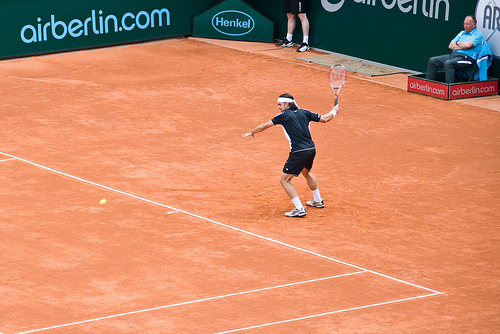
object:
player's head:
[277, 92, 294, 112]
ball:
[99, 198, 107, 204]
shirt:
[270, 109, 321, 153]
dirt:
[1, 39, 498, 332]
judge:
[426, 15, 483, 84]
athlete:
[240, 92, 340, 217]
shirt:
[451, 27, 484, 60]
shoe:
[306, 199, 325, 208]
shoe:
[283, 207, 307, 217]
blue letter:
[151, 7, 172, 27]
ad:
[18, 7, 173, 44]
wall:
[0, 0, 500, 85]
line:
[5, 270, 443, 334]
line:
[0, 153, 443, 298]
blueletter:
[20, 24, 37, 43]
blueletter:
[136, 10, 151, 30]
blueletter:
[121, 12, 136, 30]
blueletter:
[105, 14, 119, 33]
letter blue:
[19, 8, 171, 45]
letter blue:
[211, 10, 256, 37]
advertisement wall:
[190, 2, 273, 43]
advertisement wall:
[0, 0, 199, 60]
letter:
[68, 18, 84, 37]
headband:
[277, 97, 300, 109]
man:
[275, 0, 311, 53]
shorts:
[282, 0, 309, 13]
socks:
[291, 188, 322, 210]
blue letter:
[482, 5, 491, 30]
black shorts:
[282, 148, 317, 177]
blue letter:
[91, 9, 99, 34]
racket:
[327, 62, 348, 114]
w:
[332, 71, 343, 81]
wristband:
[329, 109, 337, 117]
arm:
[306, 110, 336, 123]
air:
[2, 3, 497, 331]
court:
[0, 34, 497, 334]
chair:
[455, 65, 477, 82]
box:
[405, 71, 499, 101]